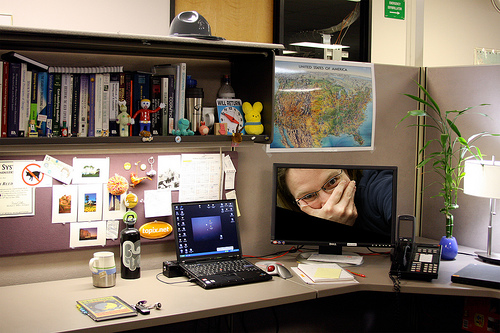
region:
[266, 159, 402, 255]
Flat screen monitor with a man's face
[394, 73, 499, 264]
Green plant in a purple vace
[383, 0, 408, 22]
Green sign with white lettering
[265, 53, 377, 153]
Map on the United States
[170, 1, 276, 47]
Strip on brown paneling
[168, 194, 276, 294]
Open laptop on the desk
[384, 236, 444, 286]
Black office phone with white note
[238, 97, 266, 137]
Little yellow bunny on the chelf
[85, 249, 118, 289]
Coffee cup on the desktop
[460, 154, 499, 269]
Desk lamp on the right of the desk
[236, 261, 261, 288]
edge of a keyboard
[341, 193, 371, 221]
part of a screen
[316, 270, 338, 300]
edge of a top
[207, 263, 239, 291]
part of a keyboard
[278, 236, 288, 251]
part of an edge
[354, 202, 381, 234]
[part of a svreen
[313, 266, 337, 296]
part of a paper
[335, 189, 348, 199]
part of a finger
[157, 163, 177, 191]
part of a apper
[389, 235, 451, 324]
a telephone on the table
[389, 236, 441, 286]
a telephone with white label on it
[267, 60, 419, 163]
a map duct taped on the wall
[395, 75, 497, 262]
a green plant in a blue color vase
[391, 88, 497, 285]
a lamp near a telephone and green plant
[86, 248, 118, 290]
a mug with a white handle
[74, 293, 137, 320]
a note book and a pen kept beside each other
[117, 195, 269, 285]
a flask is kept near the laptop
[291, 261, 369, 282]
a red color pen nearer to the note pad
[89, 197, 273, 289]
a flask and a mug kept near the laptop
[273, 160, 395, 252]
a black computer monitor on a desk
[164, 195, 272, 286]
a blaqck laptop computer on the desk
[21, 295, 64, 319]
grey surface of the desk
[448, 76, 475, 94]
grey wall of the cubicle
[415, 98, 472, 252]
a small green plant on the desk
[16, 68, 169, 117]
many books lined on a shelf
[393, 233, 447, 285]
a black telephone on the desk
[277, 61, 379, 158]
a map on the wall of the cubicle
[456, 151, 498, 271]
a smal lamp on the desk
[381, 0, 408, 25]
green sign on a white wall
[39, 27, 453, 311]
this is an office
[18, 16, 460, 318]
this is a cubicle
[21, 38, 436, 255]
this is a work space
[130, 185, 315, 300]
this is a little laptop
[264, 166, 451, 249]
this is a monitor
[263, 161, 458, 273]
there is a man on the monitor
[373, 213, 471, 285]
this is a landline phone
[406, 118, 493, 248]
this is a plant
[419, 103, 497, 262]
the plant is green and tall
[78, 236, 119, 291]
this is a coffee mugg